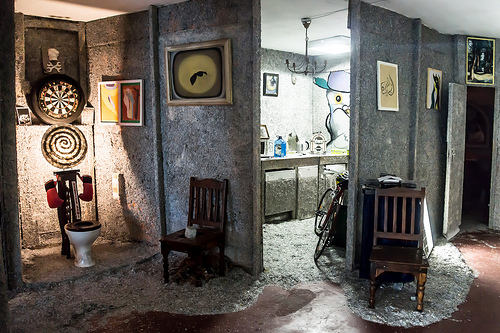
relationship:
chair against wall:
[163, 177, 225, 286] [87, 1, 262, 267]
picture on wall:
[164, 40, 233, 105] [157, 8, 258, 276]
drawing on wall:
[311, 67, 351, 157] [343, 0, 498, 276]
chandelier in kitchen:
[281, 17, 338, 75] [264, 26, 359, 227]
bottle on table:
[270, 133, 287, 156] [260, 150, 347, 227]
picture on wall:
[460, 36, 497, 91] [415, 27, 457, 199]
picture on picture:
[155, 40, 233, 110] [83, 69, 171, 155]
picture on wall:
[155, 40, 233, 110] [14, 1, 491, 273]